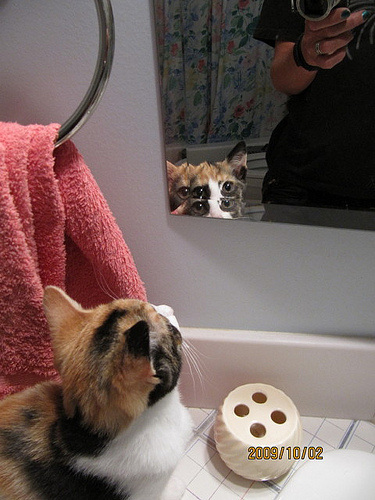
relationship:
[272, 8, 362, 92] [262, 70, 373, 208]
person wearing black shirt